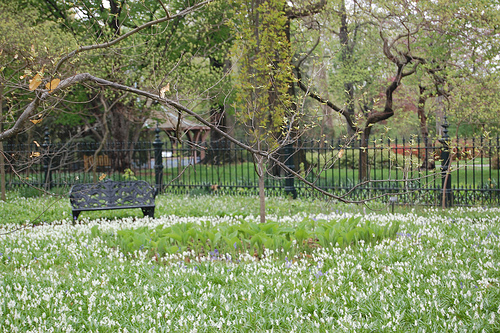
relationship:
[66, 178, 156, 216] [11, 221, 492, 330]
bench on lawn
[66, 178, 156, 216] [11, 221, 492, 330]
bench on yard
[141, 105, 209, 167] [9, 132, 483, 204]
gazebo behind fence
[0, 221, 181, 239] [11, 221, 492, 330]
flower in grass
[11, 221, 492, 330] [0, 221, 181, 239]
grass in flowers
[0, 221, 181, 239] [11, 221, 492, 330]
flowers surrounding grass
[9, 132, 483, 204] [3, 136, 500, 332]
fence around property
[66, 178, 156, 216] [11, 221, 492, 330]
bench in park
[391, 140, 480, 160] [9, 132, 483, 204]
plants behind fence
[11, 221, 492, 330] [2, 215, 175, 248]
grass with wildflowers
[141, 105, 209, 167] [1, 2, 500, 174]
gazebo in background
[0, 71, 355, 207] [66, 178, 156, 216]
branch above bench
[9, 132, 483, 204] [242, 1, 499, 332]
fence post furthest right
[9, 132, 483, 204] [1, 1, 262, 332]
fence post furthest left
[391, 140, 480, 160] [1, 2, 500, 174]
bushes in background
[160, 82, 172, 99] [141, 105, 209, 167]
object near gazebo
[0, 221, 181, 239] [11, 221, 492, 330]
flowers in grass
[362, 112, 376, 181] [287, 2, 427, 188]
brown bare tree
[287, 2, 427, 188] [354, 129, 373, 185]
tree with trunk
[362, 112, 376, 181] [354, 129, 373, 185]
brown tree trunk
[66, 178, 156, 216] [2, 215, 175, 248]
bench with flowers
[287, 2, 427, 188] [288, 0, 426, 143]
tree with branches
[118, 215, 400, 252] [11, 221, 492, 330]
patch of grass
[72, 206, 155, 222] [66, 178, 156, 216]
legs of bench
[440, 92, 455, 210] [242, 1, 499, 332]
pole to right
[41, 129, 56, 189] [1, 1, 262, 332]
pole to left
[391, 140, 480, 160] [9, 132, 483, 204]
bushes behind fence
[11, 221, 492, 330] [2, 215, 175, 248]
field with wildflowers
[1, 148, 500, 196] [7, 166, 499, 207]
field of grass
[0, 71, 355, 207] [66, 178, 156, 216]
branch over bench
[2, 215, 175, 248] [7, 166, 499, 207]
wildflowers growing in grass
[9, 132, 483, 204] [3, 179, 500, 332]
fence along park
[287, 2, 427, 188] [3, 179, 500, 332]
tree in park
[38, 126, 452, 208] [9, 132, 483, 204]
posts along fence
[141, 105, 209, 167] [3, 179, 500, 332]
building behind park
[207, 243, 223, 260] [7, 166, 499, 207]
flowers in grass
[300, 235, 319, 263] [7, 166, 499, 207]
flowers growing in grass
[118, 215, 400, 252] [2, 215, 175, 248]
area without wildflowers